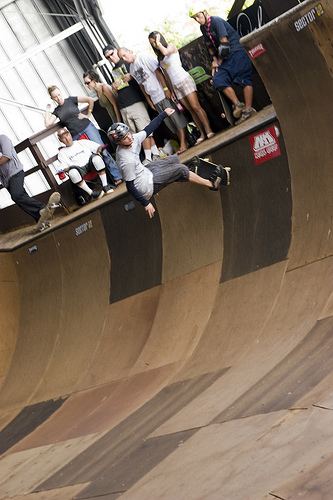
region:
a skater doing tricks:
[47, 70, 265, 240]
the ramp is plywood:
[65, 78, 269, 241]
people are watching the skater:
[25, 50, 300, 244]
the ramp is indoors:
[25, 7, 293, 277]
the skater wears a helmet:
[26, 34, 264, 243]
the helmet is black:
[64, 84, 272, 257]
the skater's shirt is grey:
[84, 107, 296, 244]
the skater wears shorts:
[79, 84, 327, 279]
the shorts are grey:
[72, 100, 244, 241]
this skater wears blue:
[174, 1, 279, 151]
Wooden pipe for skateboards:
[57, 221, 259, 355]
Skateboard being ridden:
[187, 153, 236, 192]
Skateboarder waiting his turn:
[49, 123, 115, 202]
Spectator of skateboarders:
[143, 28, 216, 144]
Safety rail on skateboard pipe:
[22, 133, 71, 213]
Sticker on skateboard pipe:
[286, 3, 327, 31]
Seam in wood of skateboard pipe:
[207, 248, 230, 291]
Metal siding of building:
[10, 15, 52, 43]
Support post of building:
[76, 15, 106, 50]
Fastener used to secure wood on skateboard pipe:
[301, 256, 310, 267]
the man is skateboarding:
[93, 117, 245, 214]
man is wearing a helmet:
[93, 109, 137, 149]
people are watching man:
[3, 11, 324, 184]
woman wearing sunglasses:
[69, 66, 108, 105]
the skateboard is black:
[175, 156, 253, 196]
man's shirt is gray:
[91, 137, 177, 210]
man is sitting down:
[44, 128, 112, 196]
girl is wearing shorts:
[154, 71, 205, 109]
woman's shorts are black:
[43, 100, 101, 135]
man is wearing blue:
[198, 24, 254, 100]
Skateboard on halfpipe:
[100, 105, 232, 199]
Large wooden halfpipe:
[0, 15, 329, 497]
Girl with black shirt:
[39, 77, 96, 143]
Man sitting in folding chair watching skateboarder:
[47, 121, 124, 210]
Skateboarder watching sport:
[187, 9, 263, 130]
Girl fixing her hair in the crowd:
[146, 24, 215, 154]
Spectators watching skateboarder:
[1, 0, 264, 218]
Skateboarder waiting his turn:
[0, 121, 64, 235]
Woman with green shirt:
[80, 68, 127, 123]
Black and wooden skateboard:
[190, 149, 234, 190]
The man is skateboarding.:
[94, 110, 227, 211]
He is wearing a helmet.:
[94, 115, 142, 159]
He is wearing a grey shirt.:
[107, 116, 237, 207]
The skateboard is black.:
[182, 145, 250, 200]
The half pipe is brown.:
[13, 212, 324, 497]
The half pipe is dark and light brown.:
[26, 146, 312, 465]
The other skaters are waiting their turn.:
[27, 14, 266, 178]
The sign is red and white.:
[244, 133, 301, 162]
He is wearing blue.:
[190, 15, 260, 109]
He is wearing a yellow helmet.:
[176, 3, 223, 34]